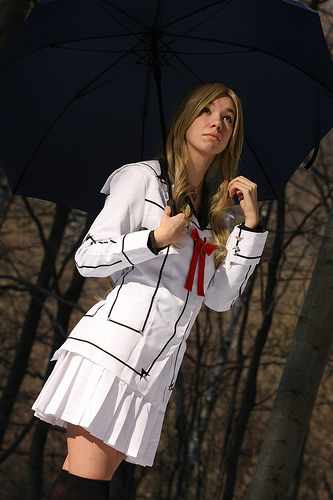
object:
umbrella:
[0, 1, 332, 211]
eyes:
[201, 108, 210, 115]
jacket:
[50, 160, 269, 397]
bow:
[185, 228, 212, 295]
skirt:
[33, 353, 167, 469]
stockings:
[72, 470, 112, 499]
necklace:
[188, 178, 204, 200]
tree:
[234, 163, 333, 500]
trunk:
[237, 212, 332, 499]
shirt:
[240, 222, 263, 232]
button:
[235, 235, 243, 241]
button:
[233, 246, 240, 252]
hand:
[160, 206, 189, 245]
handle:
[167, 199, 176, 216]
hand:
[227, 176, 260, 222]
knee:
[65, 477, 107, 499]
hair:
[164, 83, 244, 264]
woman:
[34, 85, 267, 500]